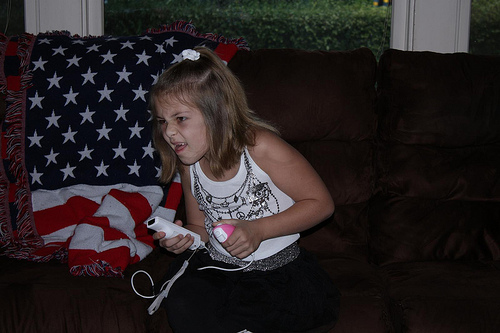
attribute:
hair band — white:
[173, 44, 203, 70]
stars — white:
[23, 51, 122, 180]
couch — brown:
[143, 43, 474, 299]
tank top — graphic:
[173, 163, 293, 266]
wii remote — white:
[145, 216, 205, 256]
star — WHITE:
[46, 108, 62, 128]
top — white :
[189, 159, 292, 258]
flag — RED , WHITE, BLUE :
[9, 28, 231, 274]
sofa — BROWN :
[3, 31, 498, 331]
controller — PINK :
[211, 220, 234, 242]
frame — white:
[403, 50, 464, 56]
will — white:
[141, 212, 201, 272]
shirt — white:
[213, 180, 259, 231]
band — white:
[179, 50, 200, 64]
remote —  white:
[141, 213, 204, 253]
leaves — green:
[104, 0, 392, 60]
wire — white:
[122, 253, 249, 331]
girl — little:
[148, 36, 341, 328]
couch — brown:
[205, 43, 497, 329]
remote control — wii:
[136, 189, 255, 286]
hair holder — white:
[140, 53, 230, 73]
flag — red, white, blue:
[27, 27, 253, 279]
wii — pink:
[211, 220, 233, 242]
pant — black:
[167, 257, 312, 330]